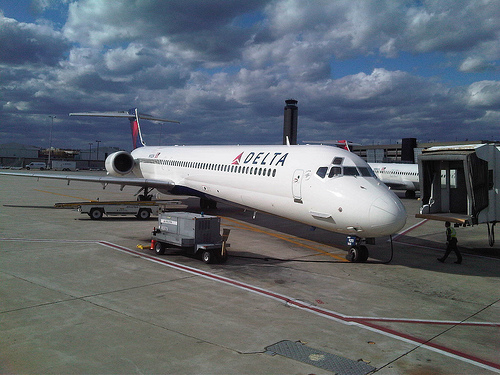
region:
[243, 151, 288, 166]
the word 'delta' on a plane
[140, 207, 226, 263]
a grey utility vehicle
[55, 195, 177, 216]
a grey utility vehicle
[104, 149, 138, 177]
engine on a plane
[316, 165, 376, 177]
windows on a cockpit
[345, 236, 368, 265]
front wheel of a plane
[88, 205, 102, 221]
wheel on a truck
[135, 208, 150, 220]
wheel on a truck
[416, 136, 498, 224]
passenger walkway for boarding plane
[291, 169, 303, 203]
door on a plane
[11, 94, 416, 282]
an airplane at a terminal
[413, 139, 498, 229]
a walkway to an airplane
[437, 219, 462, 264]
an airport worker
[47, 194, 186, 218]
a luggage cart at an airport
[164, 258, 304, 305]
red and white lines on concrete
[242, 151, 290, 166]
the word DELTA on an airplane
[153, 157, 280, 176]
windows on an airplane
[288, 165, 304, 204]
a door on an airplane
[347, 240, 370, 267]
a wheel on an airplane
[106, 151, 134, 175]
an engine on an airplane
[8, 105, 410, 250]
A plane sits on the tarmac.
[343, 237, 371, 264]
The plane's landing gear.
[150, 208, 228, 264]
The extra generator.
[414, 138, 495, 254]
The jet way is ready to be for connection.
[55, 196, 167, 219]
The baggage ramp is ready for action.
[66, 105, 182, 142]
The plane's tail.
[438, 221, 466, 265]
The person is walking by.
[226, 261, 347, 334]
The lines on the tarmac.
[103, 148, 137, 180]
The plane's engine.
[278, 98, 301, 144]
The control tower in the back.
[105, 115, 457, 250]
white airliner on tarmac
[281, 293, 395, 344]
red lines on tarmac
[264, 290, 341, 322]
white lines on tarmac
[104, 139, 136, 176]
engine on side of plane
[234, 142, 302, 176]
delta logo on plane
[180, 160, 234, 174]
row of white windows on plane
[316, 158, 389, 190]
cockpit windows on front of plane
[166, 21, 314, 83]
white clouds in sky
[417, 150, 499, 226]
loading tunnel on right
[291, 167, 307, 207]
emergency exit on plane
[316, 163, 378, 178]
The front window of a passenger plane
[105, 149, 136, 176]
Engine of a large plane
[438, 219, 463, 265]
A man wearing a safety vest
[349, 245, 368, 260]
The wheel of a plane's landing gear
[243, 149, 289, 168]
Letters on the side of a plane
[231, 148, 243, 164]
Insignia on the side of a plane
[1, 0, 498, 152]
Thick, fluffy clouds in the blue sky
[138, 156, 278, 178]
Windows in a horizontal row on a plane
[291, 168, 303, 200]
A door on a passenger plane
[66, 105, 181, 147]
Rear wings of a large plane.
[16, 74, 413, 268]
airplane on the runway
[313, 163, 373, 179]
windows on the airplane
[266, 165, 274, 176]
window on the airplane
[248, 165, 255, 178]
window on the airplane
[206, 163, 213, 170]
window on the airplane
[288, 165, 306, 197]
door on the airplane